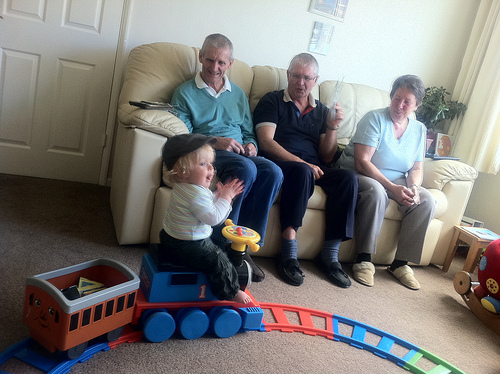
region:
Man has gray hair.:
[198, 30, 250, 80]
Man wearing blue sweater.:
[186, 83, 256, 139]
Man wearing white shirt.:
[188, 72, 248, 107]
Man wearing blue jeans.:
[228, 160, 269, 198]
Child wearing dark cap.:
[159, 124, 215, 186]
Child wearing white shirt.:
[160, 178, 242, 245]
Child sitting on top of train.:
[146, 140, 273, 284]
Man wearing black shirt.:
[283, 109, 330, 156]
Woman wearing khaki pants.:
[372, 193, 451, 255]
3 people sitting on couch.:
[107, 90, 419, 234]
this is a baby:
[156, 125, 252, 270]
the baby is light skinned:
[186, 168, 203, 179]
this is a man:
[278, 47, 344, 174]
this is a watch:
[320, 122, 345, 131]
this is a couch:
[123, 52, 170, 137]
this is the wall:
[351, 9, 443, 59]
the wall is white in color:
[362, 10, 432, 55]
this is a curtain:
[466, 28, 498, 83]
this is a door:
[13, 20, 103, 157]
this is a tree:
[427, 82, 454, 122]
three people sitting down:
[206, 28, 434, 257]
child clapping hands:
[158, 140, 240, 295]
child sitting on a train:
[134, 139, 271, 350]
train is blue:
[147, 270, 265, 347]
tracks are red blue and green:
[266, 305, 438, 372]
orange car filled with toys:
[26, 247, 133, 354]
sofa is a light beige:
[434, 167, 464, 257]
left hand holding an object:
[320, 85, 354, 135]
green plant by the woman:
[427, 78, 466, 141]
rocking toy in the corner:
[456, 244, 498, 344]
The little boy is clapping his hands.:
[148, 128, 249, 258]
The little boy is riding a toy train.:
[111, 128, 303, 361]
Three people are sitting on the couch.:
[137, 30, 467, 300]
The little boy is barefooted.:
[159, 233, 274, 321]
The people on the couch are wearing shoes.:
[224, 236, 445, 304]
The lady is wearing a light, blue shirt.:
[353, 68, 437, 206]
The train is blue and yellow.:
[132, 217, 311, 347]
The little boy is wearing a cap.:
[137, 120, 227, 198]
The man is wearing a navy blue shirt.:
[259, 50, 362, 165]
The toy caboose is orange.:
[7, 243, 152, 368]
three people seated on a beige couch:
[112, 31, 477, 272]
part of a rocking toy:
[453, 238, 499, 330]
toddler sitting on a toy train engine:
[135, 132, 263, 357]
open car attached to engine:
[22, 218, 266, 362]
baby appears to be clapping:
[213, 177, 244, 201]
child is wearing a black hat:
[161, 132, 215, 170]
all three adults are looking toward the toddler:
[155, 33, 434, 303]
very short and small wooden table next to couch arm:
[431, 159, 498, 279]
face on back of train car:
[25, 276, 70, 351]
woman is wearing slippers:
[351, 255, 418, 290]